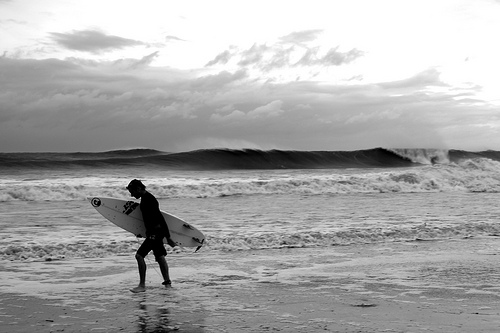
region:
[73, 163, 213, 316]
the man is holding a surfboard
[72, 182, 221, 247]
the surfboard is white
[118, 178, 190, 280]
the man is wearing a wetsuit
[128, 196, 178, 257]
the wetsuit is black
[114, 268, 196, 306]
the man's feet are wet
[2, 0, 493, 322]
the picture is in black and white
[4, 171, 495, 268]
the waves are coming to shore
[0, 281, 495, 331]
the sand is wet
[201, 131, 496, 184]
the waves are high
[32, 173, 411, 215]
the waves are white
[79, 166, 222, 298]
man walking on the beach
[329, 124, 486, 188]
large wave hitting the water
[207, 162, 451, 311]
waves coming into the shore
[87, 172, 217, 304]
man holding surfing board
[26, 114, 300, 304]
black and white photo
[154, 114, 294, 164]
water mist in the sky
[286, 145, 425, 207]
deep ocean water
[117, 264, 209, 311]
feet touch beach sand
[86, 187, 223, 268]
white surf board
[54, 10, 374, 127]
large clouds in the sky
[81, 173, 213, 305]
lone surfer on the beach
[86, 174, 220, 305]
person getting ready to surf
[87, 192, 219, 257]
white surf board carried by a man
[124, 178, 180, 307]
man in a dark wet suit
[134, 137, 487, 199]
waves rolling into the beach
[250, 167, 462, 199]
waves breaking on the shore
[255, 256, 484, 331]
waves and white foam on the beach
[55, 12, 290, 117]
clouds rolling in the sky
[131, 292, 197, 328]
reflection of man in the water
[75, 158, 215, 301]
man finishing surfing for the day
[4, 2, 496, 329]
Black and white filter.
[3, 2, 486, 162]
The sky is grey.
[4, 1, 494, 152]
The sky is cloudy.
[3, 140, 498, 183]
Big waves in the water.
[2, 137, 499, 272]
The water is choppy.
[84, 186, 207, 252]
Surfboard is white.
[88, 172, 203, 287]
Person holding a surfboard.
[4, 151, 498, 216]
The waves are white.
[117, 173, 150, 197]
Person is wearing a hat.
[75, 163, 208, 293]
One surfer on the beach.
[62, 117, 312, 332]
the man holding a surfing board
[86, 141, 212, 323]
the man holding a surfing board